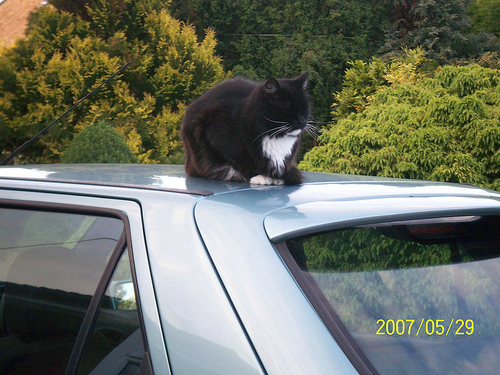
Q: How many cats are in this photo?
A: One.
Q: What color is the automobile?
A: Steel.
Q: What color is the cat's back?
A: Black.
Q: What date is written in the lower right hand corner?
A: 2007/05/29.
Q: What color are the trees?
A: Green.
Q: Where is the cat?
A: On top of the vehicle.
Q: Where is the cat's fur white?
A: On its underside.